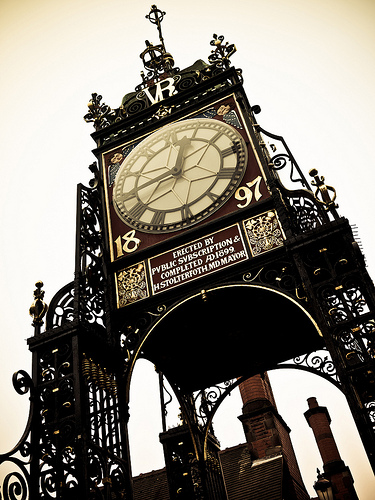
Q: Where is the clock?
A: On the tower.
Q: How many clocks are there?
A: One.